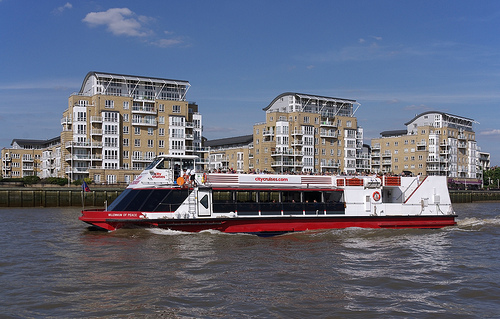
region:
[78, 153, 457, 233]
The boat is red and white.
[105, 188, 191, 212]
The boat has several windows.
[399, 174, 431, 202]
There is a staircase to the upperlevel.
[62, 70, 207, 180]
The building sits on the water.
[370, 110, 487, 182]
The building has a waterfront view.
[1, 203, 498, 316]
The water has some mild waves.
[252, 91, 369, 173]
The building has many windows.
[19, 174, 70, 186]
Shrubs border the building.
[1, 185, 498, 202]
A dock offers people a walk along the water.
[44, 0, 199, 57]
There is a wispy cloud in the sky.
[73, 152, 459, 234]
A passenger speed boat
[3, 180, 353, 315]
A calm water body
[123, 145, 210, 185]
Captain's cabin on the top of the boat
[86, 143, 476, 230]
Two storied tourist boat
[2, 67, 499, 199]
Multistoried condominiums on the shore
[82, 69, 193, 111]
Penthouse on the top floor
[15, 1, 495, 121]
A few white clouds in the sky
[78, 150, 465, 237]
Red and white boat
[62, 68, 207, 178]
Light brown and white apartments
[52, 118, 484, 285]
this is a large ferry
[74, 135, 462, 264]
a long boat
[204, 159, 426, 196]
there are people on the upper deck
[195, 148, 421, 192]
people sitting on the upper deck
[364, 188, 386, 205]
an orange life ring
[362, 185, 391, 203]
an orange life saver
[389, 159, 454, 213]
the side of a staircase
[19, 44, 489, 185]
brown and white apartment buildings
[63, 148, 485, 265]
the boat is red and white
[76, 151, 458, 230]
A boat in the water.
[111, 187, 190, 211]
The window on the boat.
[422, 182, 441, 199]
Part of the side of the boat.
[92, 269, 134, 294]
Part of the water.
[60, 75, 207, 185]
A large building.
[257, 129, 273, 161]
Part of a building.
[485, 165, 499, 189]
Part of a bush.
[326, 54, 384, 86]
Part of the sky.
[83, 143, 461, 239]
a cruise ship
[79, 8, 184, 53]
a white cloud in the sky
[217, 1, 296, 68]
the sky is clear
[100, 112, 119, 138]
windows on the building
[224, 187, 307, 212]
windows on the ship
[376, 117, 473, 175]
a building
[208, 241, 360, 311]
the lakes water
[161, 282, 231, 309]
small waves in the water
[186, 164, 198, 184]
people on the cruise ship